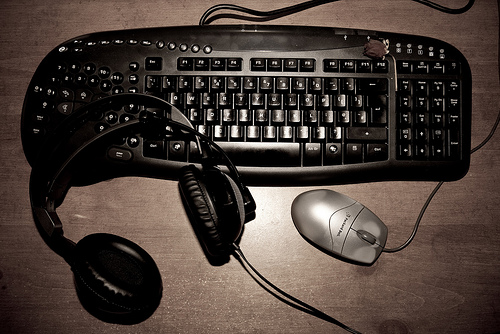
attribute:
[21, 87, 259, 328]
headphones — black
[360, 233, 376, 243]
wheel — scroll wheel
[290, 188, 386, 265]
mouse — silver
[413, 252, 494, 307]
table — wooden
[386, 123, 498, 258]
cord — gray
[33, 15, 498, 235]
keyboard — black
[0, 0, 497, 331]
desk — brown, wooden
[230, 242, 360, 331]
cord — black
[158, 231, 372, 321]
headphones — black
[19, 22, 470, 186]
keyboard — black